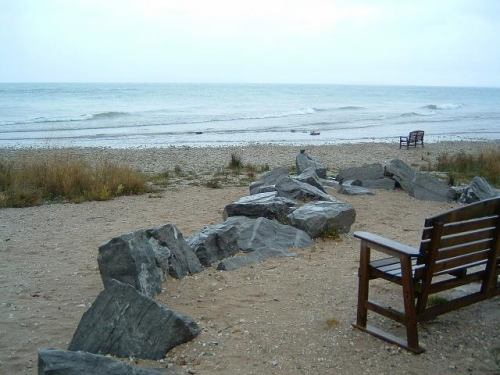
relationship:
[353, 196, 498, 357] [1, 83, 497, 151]
bench toward ocean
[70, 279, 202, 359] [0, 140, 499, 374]
rock on bench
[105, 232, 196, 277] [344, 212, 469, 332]
gray rock by wooden bench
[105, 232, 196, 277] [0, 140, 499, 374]
gray rock by bench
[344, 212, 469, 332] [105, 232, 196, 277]
wooden bench by gray rock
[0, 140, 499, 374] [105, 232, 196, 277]
bench by gray rock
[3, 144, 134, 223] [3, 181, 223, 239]
grass by beach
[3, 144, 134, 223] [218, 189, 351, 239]
grass near rock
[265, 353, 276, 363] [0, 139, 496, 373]
rock on sand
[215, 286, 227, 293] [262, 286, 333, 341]
tiny rock on sand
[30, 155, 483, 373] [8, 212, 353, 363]
rocks on beach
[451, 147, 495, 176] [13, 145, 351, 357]
grass on beach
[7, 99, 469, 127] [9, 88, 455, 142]
waves in water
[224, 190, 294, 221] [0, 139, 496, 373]
rock on sand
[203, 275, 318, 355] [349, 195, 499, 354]
sand on wooden bench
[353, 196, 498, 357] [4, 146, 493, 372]
bench in foreground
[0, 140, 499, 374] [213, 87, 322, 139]
bench by water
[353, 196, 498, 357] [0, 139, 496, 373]
bench by sand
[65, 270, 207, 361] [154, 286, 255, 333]
rock on sand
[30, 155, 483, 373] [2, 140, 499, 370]
rocks on beach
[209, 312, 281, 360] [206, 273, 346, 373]
white rocks on sand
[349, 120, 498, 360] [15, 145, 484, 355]
two benches on a beach